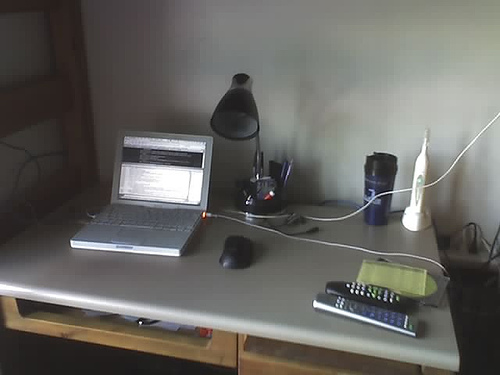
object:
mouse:
[219, 235, 252, 269]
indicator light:
[202, 212, 206, 219]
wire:
[206, 212, 450, 276]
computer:
[69, 129, 213, 257]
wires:
[439, 222, 500, 281]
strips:
[437, 249, 499, 269]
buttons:
[346, 281, 401, 303]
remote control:
[312, 293, 419, 338]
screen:
[117, 135, 207, 205]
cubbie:
[13, 300, 213, 352]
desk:
[0, 185, 461, 375]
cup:
[363, 151, 398, 225]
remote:
[324, 280, 410, 313]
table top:
[0, 185, 460, 372]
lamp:
[209, 72, 282, 214]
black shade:
[287, 81, 323, 204]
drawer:
[1, 296, 238, 369]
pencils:
[279, 157, 293, 188]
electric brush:
[409, 128, 430, 213]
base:
[401, 206, 433, 232]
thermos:
[363, 151, 398, 226]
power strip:
[438, 249, 500, 272]